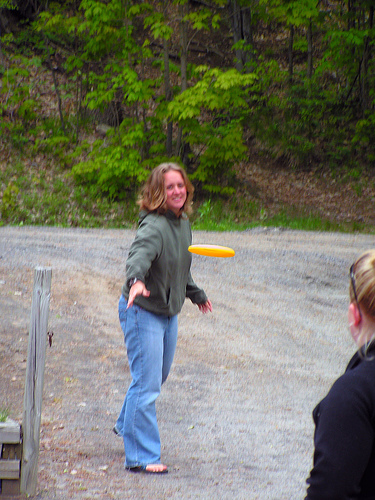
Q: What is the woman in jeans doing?
A: Throwing a frisbee.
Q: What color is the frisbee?
A: Yellow.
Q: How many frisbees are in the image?
A: One.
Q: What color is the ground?
A: Gray and brown.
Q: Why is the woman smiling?
A: She is happy.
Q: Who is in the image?
A: Two women.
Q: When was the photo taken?
A: Daytime.